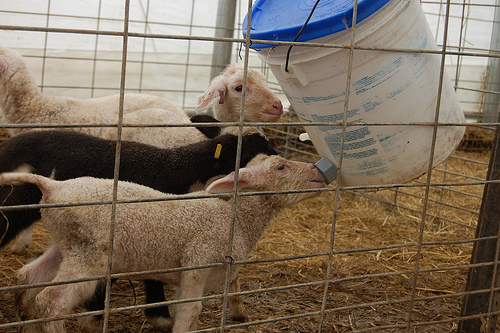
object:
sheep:
[0, 129, 279, 255]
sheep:
[197, 66, 283, 123]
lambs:
[0, 154, 326, 333]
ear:
[206, 168, 254, 193]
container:
[242, 1, 468, 191]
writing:
[301, 91, 350, 103]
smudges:
[392, 161, 424, 181]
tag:
[214, 144, 223, 159]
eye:
[278, 164, 284, 170]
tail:
[0, 172, 55, 188]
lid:
[240, 0, 391, 49]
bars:
[0, 24, 500, 59]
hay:
[266, 214, 447, 331]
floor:
[1, 152, 499, 332]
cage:
[0, 0, 500, 331]